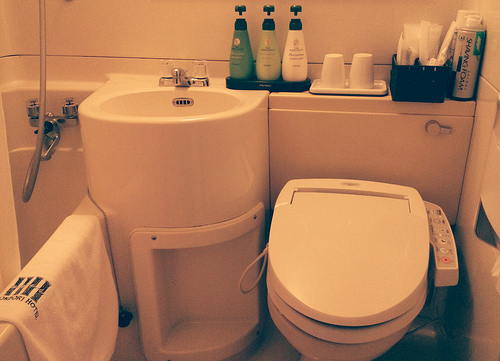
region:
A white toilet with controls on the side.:
[264, 174, 459, 359]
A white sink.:
[79, 57, 269, 145]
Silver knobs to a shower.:
[20, 94, 77, 123]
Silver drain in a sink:
[170, 94, 193, 108]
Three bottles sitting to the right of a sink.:
[225, 4, 307, 84]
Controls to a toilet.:
[419, 197, 460, 289]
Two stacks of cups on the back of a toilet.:
[321, 50, 373, 92]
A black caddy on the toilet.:
[387, 53, 449, 105]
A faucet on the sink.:
[168, 69, 194, 88]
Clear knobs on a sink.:
[156, 54, 207, 79]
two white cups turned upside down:
[319, 52, 375, 87]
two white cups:
[319, 52, 375, 90]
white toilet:
[267, 94, 476, 359]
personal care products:
[227, 2, 307, 81]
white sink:
[75, 57, 269, 359]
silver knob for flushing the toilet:
[422, 119, 455, 138]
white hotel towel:
[0, 213, 120, 359]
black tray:
[224, 75, 310, 90]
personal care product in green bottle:
[227, 2, 253, 80]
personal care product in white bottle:
[281, 4, 308, 81]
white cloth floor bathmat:
[0, 213, 120, 359]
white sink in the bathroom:
[77, 58, 269, 359]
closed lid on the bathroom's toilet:
[266, 177, 430, 359]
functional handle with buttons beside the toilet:
[429, 192, 458, 286]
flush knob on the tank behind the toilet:
[426, 119, 452, 138]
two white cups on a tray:
[308, 51, 387, 96]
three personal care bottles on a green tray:
[225, 2, 309, 89]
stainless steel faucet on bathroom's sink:
[157, 67, 208, 87]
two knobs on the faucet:
[158, 60, 205, 77]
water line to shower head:
[20, 1, 77, 202]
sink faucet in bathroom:
[149, 51, 216, 100]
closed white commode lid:
[263, 168, 442, 329]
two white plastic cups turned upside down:
[309, 43, 386, 98]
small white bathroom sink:
[82, 70, 274, 237]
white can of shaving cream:
[450, 8, 492, 116]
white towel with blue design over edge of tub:
[4, 197, 107, 358]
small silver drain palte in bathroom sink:
[164, 88, 203, 110]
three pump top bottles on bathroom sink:
[225, 1, 317, 96]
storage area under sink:
[125, 208, 262, 360]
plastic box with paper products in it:
[385, 7, 462, 116]